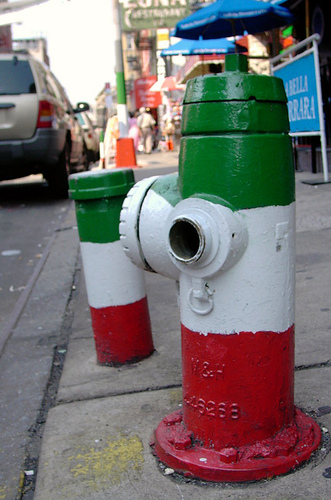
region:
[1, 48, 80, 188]
a vehicle on the road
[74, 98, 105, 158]
a vehicle on the road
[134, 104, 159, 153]
a person on the road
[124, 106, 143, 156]
a person on the road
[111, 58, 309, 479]
a hydrant on the road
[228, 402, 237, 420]
the number 8 on a hydrant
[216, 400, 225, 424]
the number 6 on a hydrant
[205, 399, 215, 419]
the number 2 on a hydrant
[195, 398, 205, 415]
the number 6 on a hydrant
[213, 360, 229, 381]
a letter H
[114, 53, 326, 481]
red, white and green fire hydrant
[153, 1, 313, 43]
blue umbrella by the building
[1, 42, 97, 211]
cars parked on city street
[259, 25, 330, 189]
blue and silver store sign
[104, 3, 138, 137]
light pole on the sidewalk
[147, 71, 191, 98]
red and white umbrella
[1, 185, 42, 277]
black paved city street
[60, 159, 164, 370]
red, white and green pole in sidewalk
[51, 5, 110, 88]
white cloudy sky in the distance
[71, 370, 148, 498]
concrete sidewalk by fire hydrant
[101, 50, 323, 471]
A red, green and white fire hydrant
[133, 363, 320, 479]
The fire hydrant is bolted to the ground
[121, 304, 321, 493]
The fire hydrant sits on top of cement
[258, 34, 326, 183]
A blue and white sign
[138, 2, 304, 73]
Two blue umbrellas with white writing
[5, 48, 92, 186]
A beige SUV parked along the curb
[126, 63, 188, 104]
A red sign with white letters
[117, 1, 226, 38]
Green sign with white lettering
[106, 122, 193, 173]
An orange block on the cement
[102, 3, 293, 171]
The shopping area has various signs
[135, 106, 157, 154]
man walking in khaki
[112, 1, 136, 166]
white, green, and gray pole with a red base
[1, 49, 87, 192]
gold suv parked near curb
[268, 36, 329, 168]
blue sign with grey frame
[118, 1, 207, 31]
green sign with white lettering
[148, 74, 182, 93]
red and white striped umbrella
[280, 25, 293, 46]
green and orange neon sign in the window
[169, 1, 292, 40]
closest blue umbrella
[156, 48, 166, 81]
black sign with large white letters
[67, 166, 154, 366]
shorter green, white, and red pole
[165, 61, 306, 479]
an Italian flag theme fire hydrant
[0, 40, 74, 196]
a big tan car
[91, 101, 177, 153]
a bunch of people in the background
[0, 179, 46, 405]
the cement road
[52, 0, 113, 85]
the bright sunlight sky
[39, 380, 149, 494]
the cement floor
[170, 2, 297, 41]
a blue umbrella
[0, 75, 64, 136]
the backside of a car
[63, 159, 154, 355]
a red white and green pole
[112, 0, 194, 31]
a green sign